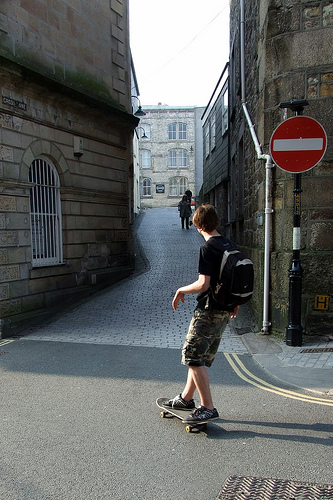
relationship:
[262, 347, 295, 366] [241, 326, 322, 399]
stone on sidewalk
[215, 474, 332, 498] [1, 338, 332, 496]
grate in middle of road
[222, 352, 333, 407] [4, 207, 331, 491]
double lines on side of road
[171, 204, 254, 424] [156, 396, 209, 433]
boy balancing on board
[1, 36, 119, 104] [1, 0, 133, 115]
mold on wall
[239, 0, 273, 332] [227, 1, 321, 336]
drain pipe on wall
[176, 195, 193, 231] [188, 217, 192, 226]
woman holding bag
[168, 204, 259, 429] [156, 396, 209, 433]
boy standing on board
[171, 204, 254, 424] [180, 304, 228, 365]
boy wearing cargo pants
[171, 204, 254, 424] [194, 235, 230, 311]
boy wearing dark shirt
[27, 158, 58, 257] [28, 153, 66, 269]
bars on window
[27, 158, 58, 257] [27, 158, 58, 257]
bars on bars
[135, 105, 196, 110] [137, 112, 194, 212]
roof on building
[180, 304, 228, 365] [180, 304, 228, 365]
cargo pants on cargo pants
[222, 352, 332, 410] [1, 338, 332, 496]
double lines on road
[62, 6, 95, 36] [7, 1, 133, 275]
surface of wall